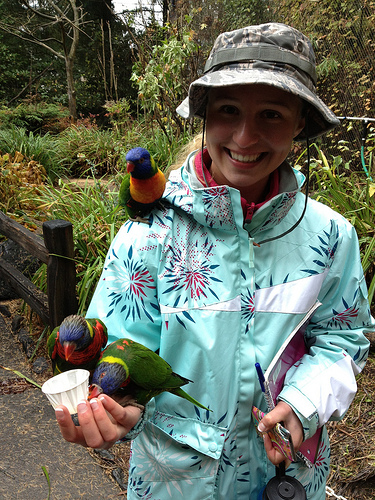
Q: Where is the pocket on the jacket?
A: Beneath birds.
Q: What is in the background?
A: Wooden fence.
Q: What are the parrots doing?
A: Eating.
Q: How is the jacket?
A: Flower pattern.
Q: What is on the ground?
A: Stones.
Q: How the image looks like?
A: Good.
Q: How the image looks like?
A: Good.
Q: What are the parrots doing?
A: Eating.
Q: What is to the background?
A: Trees.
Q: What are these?
A: Bird.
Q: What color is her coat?
A: Blue.